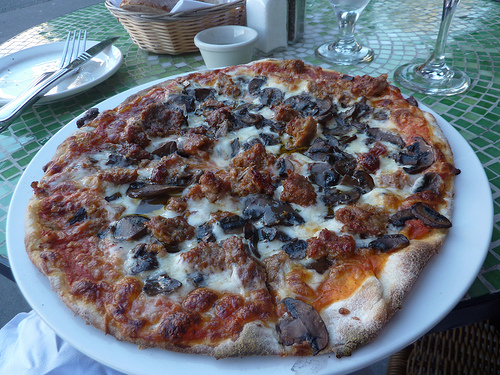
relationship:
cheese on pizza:
[193, 197, 221, 221] [25, 57, 459, 360]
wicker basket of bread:
[99, 1, 266, 61] [119, 3, 184, 16]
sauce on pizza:
[160, 195, 309, 288] [43, 40, 465, 374]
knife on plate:
[0, 34, 119, 125] [2, 40, 121, 105]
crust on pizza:
[333, 260, 418, 344] [25, 57, 459, 360]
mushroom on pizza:
[276, 297, 328, 354] [25, 57, 459, 360]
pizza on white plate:
[25, 57, 459, 360] [5, 80, 494, 374]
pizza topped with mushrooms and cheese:
[25, 57, 459, 360] [66, 75, 442, 310]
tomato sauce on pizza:
[93, 81, 375, 240] [59, 3, 433, 370]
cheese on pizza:
[34, 56, 459, 362] [25, 57, 459, 360]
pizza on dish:
[25, 57, 459, 360] [6, 67, 491, 373]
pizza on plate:
[25, 57, 459, 360] [445, 137, 497, 288]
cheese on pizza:
[73, 271, 106, 308] [25, 57, 459, 360]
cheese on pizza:
[69, 130, 112, 141] [25, 57, 459, 360]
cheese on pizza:
[361, 71, 393, 106] [25, 57, 459, 360]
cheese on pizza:
[165, 302, 202, 349] [25, 57, 459, 360]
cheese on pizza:
[213, 269, 240, 291] [25, 57, 459, 360]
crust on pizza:
[333, 260, 381, 327] [25, 57, 459, 360]